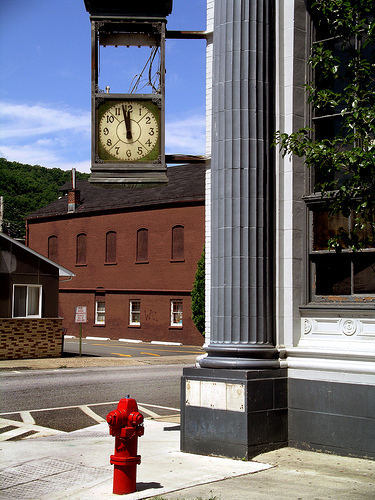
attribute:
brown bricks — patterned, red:
[1, 323, 66, 357]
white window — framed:
[8, 285, 44, 321]